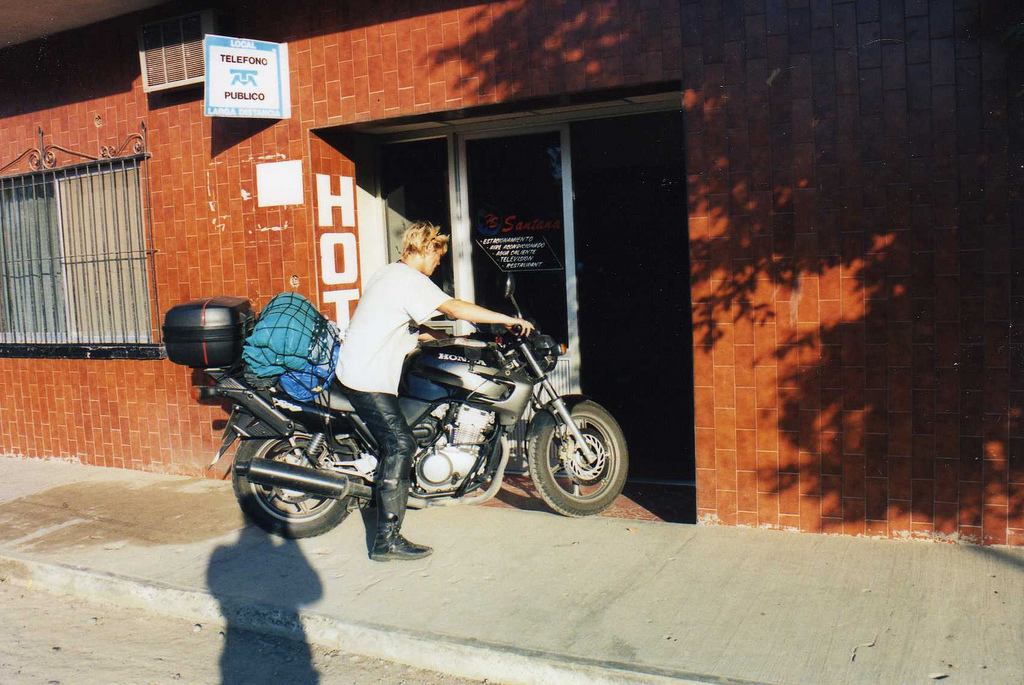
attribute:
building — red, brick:
[1, 14, 1008, 657]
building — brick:
[4, 0, 1023, 523]